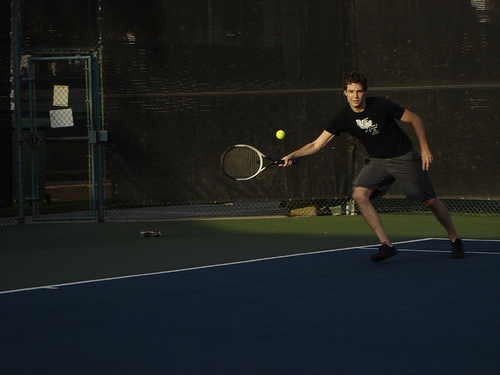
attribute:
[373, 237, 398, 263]
sneakers — black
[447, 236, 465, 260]
sneakers — black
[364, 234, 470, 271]
shoes — black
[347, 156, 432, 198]
shorts — nice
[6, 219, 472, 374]
court — green, purple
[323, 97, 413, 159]
shirt — black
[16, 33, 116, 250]
door — metal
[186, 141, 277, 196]
racket — black, white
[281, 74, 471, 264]
person — male, grown 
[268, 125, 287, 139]
ball — green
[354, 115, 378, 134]
symbol — white